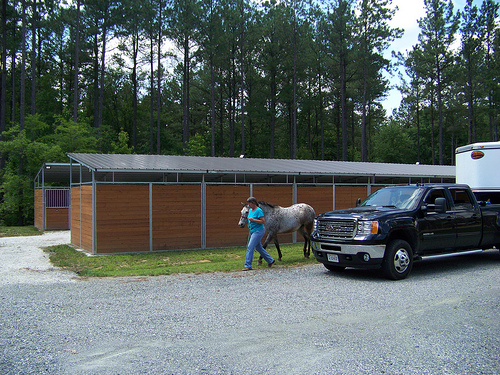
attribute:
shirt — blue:
[242, 211, 263, 238]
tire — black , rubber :
[384, 245, 410, 287]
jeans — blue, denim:
[245, 229, 275, 270]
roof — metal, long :
[81, 140, 488, 183]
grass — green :
[135, 241, 226, 294]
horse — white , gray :
[234, 196, 319, 261]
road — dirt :
[0, 226, 498, 373]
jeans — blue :
[247, 227, 272, 264]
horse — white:
[236, 198, 316, 263]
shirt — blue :
[240, 211, 265, 226]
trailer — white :
[454, 140, 499, 191]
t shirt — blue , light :
[241, 206, 271, 236]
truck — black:
[306, 181, 499, 278]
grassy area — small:
[76, 232, 223, 323]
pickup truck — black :
[308, 181, 498, 278]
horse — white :
[233, 199, 320, 254]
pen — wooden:
[66, 150, 456, 255]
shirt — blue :
[235, 202, 270, 238]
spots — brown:
[300, 205, 314, 215]